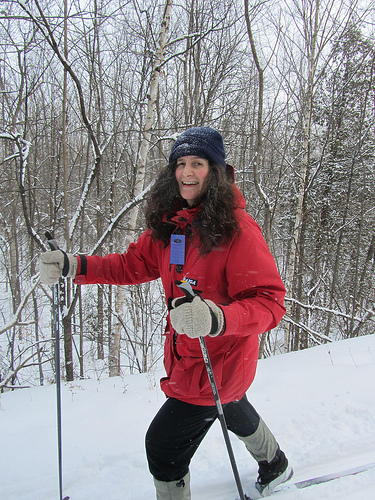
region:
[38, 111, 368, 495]
A woman is skiing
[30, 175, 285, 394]
Woman is wearing a red coat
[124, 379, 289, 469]
Woman is wearing black pants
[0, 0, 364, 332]
Snow is covering the trees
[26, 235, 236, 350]
Woman's gloves are gray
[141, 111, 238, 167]
Woman is wearing a dark blue knit cap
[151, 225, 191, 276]
A blue tag is on the woman's coat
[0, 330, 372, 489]
Snow is covering the ground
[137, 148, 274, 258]
Woman's hair is dark colored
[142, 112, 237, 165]
Snow is on the woman's knit cap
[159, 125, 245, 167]
Woman wearing stocking cap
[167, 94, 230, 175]
Stocking cap is black on woman's head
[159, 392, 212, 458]
Woman wearing black pants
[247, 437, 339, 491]
Woman wearing cross country skis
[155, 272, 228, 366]
Woman wearing gray mittens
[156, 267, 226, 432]
Woman holding ski poles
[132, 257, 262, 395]
Woman wearing red jacket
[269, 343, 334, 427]
Snow covering ground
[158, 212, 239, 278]
Blue tag attached to woman's jacket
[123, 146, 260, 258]
Woman has long dark hair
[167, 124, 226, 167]
Hat on the woman's head.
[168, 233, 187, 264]
Blue tag hanging on the woman's coat.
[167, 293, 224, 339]
Beige glove on the woman's right hand.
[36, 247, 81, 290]
Beige glove on the woman's left hand.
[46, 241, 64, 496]
Ski pole in the woman's left hand.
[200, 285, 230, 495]
Ski pole in the woman's right hand.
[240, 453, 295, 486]
Left boot on the ski.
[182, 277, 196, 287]
Black and white label on the woman's jacket.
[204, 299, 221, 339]
Black ski pole strap on the woman's right hand.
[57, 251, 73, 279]
Black ski pole strap on the woman's left hand.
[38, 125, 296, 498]
Woman in a red winter jacket.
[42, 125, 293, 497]
Woman wearing a snow winter hat on skis.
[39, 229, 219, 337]
Gloves on the woman's hands.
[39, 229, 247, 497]
Ski poles in the woman's hands.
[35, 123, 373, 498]
Woman skiing on snowy hill.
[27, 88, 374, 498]
Woman skiing at a ski resort.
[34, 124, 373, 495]
Woman in a ski competition with blue tag.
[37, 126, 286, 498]
Woman holding two ski poles.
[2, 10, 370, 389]
Leafless trees covered with snow.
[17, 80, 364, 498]
Woman walking with skis on feet.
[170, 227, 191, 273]
A name tag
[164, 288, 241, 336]
A glove for cold weather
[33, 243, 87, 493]
Ski stick to help you move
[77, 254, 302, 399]
A jacket worn by a woman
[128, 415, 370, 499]
A ski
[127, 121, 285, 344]
A woman with curly hair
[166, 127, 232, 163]
A hat to keep your ears warm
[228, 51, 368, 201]
Trees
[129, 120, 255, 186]
A hat to keep you warm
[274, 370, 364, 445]
Snow